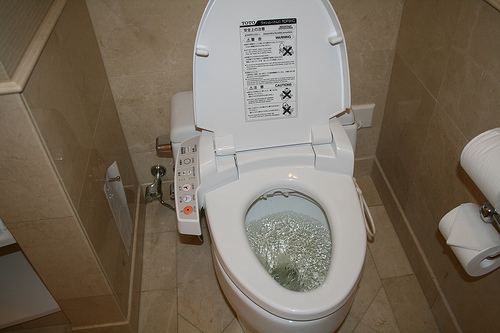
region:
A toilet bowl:
[231, 174, 354, 291]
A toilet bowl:
[254, 196, 306, 273]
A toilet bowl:
[246, 160, 318, 268]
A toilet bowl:
[251, 234, 323, 327]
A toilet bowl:
[267, 165, 302, 227]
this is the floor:
[155, 246, 197, 313]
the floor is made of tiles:
[137, 249, 196, 328]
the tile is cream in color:
[368, 252, 398, 267]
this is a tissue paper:
[435, 200, 499, 279]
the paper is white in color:
[444, 220, 470, 240]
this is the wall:
[401, 67, 441, 158]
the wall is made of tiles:
[400, 67, 437, 119]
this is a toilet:
[159, 0, 392, 331]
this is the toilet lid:
[211, 27, 308, 99]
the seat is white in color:
[333, 190, 361, 247]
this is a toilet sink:
[221, 162, 350, 307]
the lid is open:
[234, 175, 344, 280]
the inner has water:
[273, 215, 319, 270]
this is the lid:
[317, 68, 339, 111]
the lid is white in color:
[311, 60, 337, 116]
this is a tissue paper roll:
[428, 210, 498, 275]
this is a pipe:
[139, 164, 167, 204]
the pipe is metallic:
[146, 168, 167, 202]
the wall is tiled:
[413, 45, 477, 122]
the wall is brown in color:
[406, 16, 468, 95]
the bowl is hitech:
[143, 110, 401, 280]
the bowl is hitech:
[146, 130, 283, 304]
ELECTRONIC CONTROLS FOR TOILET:
[166, 139, 205, 236]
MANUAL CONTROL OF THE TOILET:
[153, 127, 180, 160]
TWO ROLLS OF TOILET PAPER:
[433, 118, 498, 300]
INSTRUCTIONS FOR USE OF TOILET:
[236, 16, 305, 122]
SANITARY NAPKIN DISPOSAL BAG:
[93, 164, 133, 255]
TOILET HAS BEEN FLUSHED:
[214, 170, 369, 324]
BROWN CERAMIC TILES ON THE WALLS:
[368, 13, 443, 182]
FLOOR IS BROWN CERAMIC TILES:
[68, 231, 225, 326]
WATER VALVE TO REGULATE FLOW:
[142, 161, 172, 211]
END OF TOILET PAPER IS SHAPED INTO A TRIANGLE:
[426, 203, 489, 251]